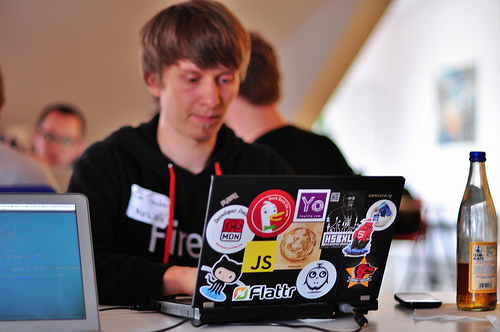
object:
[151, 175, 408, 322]
laptop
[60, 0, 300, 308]
man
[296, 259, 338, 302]
stickers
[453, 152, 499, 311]
bottle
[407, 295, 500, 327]
table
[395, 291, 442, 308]
phone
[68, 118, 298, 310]
hoodie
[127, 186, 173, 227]
tag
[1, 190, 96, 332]
monitor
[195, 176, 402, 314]
screen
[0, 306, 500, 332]
desk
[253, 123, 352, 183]
shirt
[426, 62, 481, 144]
picture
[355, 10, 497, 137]
wall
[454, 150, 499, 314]
drink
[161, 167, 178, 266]
strings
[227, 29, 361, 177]
people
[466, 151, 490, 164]
top